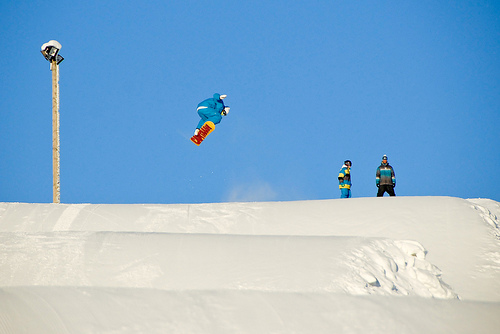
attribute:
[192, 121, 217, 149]
snowboard — red, yellow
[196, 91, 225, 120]
jacket — blue, multicolored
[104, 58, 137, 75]
sky — blue, clear, cloudless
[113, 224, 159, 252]
ground — white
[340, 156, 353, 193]
man — watching, standing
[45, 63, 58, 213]
pole — tan, wooden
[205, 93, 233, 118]
outfit — blue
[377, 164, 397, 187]
clothes — blue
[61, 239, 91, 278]
snow — white, bright, deep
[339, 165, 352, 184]
coat — blue, yellow